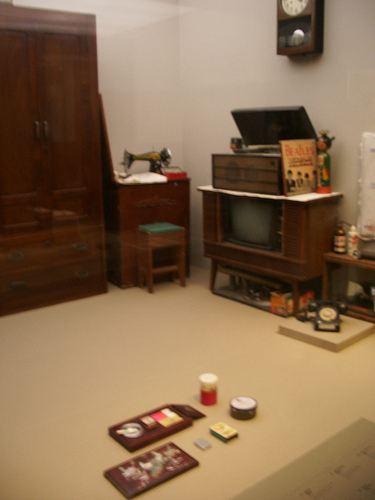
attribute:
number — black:
[293, 4, 301, 15]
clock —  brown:
[270, 1, 326, 64]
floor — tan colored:
[110, 302, 162, 343]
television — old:
[218, 190, 280, 250]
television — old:
[194, 184, 346, 308]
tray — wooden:
[107, 403, 193, 452]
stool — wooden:
[136, 221, 186, 292]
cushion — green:
[138, 220, 182, 232]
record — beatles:
[278, 133, 323, 189]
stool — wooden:
[133, 228, 216, 299]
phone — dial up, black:
[285, 292, 354, 340]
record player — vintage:
[205, 105, 334, 195]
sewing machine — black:
[122, 147, 185, 224]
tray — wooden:
[102, 402, 199, 452]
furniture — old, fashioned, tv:
[206, 159, 335, 314]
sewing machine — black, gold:
[118, 145, 173, 182]